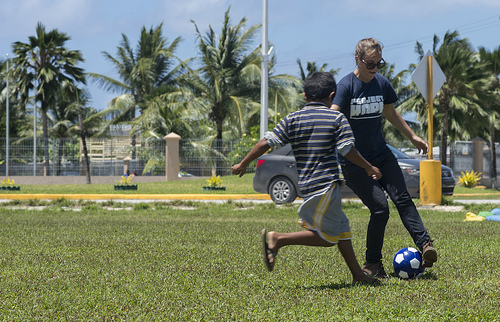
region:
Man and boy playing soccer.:
[226, 28, 443, 288]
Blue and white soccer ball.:
[390, 246, 431, 284]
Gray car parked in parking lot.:
[246, 135, 456, 205]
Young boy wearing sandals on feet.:
[253, 228, 383, 290]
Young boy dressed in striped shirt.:
[262, 101, 357, 200]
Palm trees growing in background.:
[16, 9, 240, 172]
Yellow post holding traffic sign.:
[408, 50, 460, 207]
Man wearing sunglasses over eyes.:
[357, 55, 391, 72]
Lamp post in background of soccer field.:
[1, 46, 46, 183]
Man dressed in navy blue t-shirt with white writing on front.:
[333, 71, 406, 166]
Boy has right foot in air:
[243, 209, 335, 262]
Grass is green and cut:
[8, 214, 241, 316]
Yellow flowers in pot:
[191, 170, 224, 195]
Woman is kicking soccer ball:
[345, 42, 429, 283]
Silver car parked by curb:
[260, 139, 453, 199]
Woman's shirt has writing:
[347, 90, 391, 122]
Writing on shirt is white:
[346, 92, 396, 128]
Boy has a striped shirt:
[278, 105, 338, 180]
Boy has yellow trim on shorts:
[295, 195, 356, 245]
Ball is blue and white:
[388, 243, 425, 280]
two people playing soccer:
[193, 24, 440, 316]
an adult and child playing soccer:
[257, 13, 444, 316]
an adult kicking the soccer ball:
[239, 7, 494, 309]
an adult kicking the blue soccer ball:
[272, 24, 493, 289]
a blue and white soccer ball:
[382, 222, 464, 320]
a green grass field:
[57, 222, 232, 320]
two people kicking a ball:
[233, 23, 490, 318]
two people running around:
[203, 12, 497, 319]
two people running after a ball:
[182, 10, 498, 274]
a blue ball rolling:
[298, 179, 448, 318]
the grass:
[138, 235, 234, 319]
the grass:
[123, 232, 173, 288]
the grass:
[108, 256, 150, 318]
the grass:
[116, 237, 184, 316]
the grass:
[123, 302, 165, 318]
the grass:
[164, 290, 206, 318]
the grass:
[185, 276, 217, 316]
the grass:
[157, 267, 198, 312]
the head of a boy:
[293, 67, 346, 109]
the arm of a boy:
[237, 110, 294, 165]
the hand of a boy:
[226, 160, 251, 179]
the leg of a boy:
[278, 177, 345, 249]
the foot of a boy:
[263, 224, 286, 271]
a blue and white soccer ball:
[387, 239, 429, 281]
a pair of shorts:
[292, 177, 362, 247]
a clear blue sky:
[0, 0, 497, 130]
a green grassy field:
[0, 178, 499, 320]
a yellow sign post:
[421, 52, 440, 157]